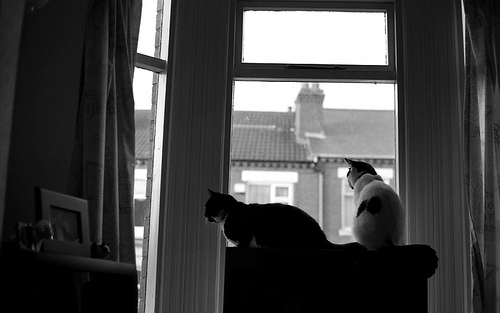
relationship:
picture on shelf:
[27, 182, 92, 253] [31, 250, 137, 291]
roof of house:
[236, 106, 396, 164] [233, 108, 403, 246]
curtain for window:
[3, 8, 138, 262] [123, 14, 179, 272]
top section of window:
[129, 6, 172, 65] [123, 14, 179, 272]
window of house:
[123, 14, 179, 272] [233, 108, 403, 246]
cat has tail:
[334, 152, 406, 260] [382, 234, 444, 277]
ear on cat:
[342, 151, 354, 178] [334, 152, 406, 260]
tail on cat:
[382, 234, 444, 277] [334, 152, 406, 260]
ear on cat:
[205, 188, 218, 200] [195, 183, 364, 260]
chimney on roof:
[290, 83, 325, 142] [236, 106, 396, 164]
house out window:
[233, 108, 403, 246] [123, 14, 179, 272]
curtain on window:
[3, 8, 138, 262] [123, 14, 179, 272]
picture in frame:
[27, 182, 92, 253] [32, 187, 109, 260]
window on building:
[265, 181, 302, 208] [229, 154, 394, 239]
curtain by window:
[3, 8, 138, 262] [123, 14, 179, 272]